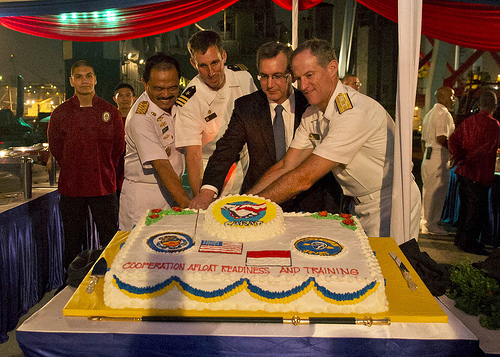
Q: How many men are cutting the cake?
A: Four.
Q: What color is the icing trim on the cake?
A: Blue and yellow.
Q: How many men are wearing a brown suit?
A: One.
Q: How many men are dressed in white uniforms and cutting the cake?
A: Three.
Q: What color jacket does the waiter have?
A: Dark red.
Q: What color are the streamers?
A: Red, white and blue.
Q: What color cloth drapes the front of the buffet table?
A: Blue.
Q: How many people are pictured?
A: 8.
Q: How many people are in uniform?
A: 4.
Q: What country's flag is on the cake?
A: US.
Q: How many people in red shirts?
A: 2.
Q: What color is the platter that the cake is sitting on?
A: Yellow.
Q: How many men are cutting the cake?
A: 4.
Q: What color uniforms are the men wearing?
A: White.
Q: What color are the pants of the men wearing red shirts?
A: Black.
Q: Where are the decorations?
A: Overhead.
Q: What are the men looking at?
A: Cake.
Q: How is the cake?
A: Decorated.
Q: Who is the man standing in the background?
A: Waiter.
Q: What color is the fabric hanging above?
A: Red.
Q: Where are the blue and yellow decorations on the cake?
A: Front side.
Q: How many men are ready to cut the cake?
A: Four.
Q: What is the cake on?
A: Table.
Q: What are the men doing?
A: Cutting cake.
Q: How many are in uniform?
A: 4.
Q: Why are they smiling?
A: They are happy.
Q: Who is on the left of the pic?
A: Man in red.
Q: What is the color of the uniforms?
A: White.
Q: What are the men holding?
A: Knife.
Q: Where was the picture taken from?
A: Reception.